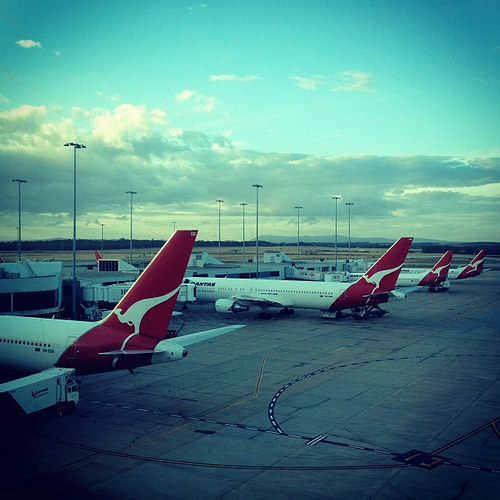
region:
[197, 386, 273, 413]
yellow line on tarmac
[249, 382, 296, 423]
white round lines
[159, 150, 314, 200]
ominous dark clouds in the sky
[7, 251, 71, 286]
top of white building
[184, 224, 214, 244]
white spot on tip of plane's tail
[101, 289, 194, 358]
white kangaroo on plane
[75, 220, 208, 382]
red paint on wing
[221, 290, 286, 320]
silver wings on plane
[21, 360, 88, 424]
white truck on tarmac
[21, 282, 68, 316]
wide window in building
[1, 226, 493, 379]
planes are white with red tails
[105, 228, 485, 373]
planes have white kangaroo on tail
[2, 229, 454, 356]
small windows on plane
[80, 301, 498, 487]
painted lines on airport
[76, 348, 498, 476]
white dotted lines on runway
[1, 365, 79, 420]
truck beside plane tail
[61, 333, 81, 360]
door next to truck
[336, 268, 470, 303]
back three planes have doors on tail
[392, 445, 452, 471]
black box with letters C1 in it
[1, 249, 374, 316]
airport terminal with planes at it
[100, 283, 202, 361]
design on tail fin of aircraft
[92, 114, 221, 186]
large white cloud in sky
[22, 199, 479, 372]
row of aircraft parked on runway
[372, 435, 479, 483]
markings on aircraft runway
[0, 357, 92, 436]
white truck parked beside aircraft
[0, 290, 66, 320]
window on side of building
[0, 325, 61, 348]
row of windows on side of aircraft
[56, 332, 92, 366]
red and white metal door on aircraft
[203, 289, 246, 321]
jet aircraft engine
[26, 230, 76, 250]
row of trees with green leaves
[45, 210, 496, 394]
Planes with red and white tails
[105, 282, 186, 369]
White kangaroo logo on tail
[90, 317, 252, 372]
Tail wings of plane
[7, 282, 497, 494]
Tarmac planes are parked on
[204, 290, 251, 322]
Engine of red and white plane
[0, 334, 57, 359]
Side windows of red and white plane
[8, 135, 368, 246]
Lights on poles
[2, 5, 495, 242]
White and blue cloudy skies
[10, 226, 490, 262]
Treeline in the distance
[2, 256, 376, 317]
Terminal of the airport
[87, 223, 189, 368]
the tailfin on the plane is red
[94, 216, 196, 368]
there is a kangaroo on the fin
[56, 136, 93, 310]
lights on the airfield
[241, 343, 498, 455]
markings on the airfield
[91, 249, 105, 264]
a flag in the distance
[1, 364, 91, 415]
a truck on the tarmac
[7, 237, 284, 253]
mountains in the distance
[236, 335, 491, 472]
the markings are black and white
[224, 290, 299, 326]
the wing on the side of the plane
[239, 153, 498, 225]
the cloud in the sky is dark